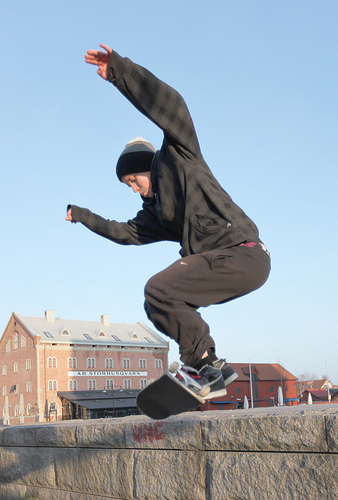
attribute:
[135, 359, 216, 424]
skateboard — inverted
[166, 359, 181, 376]
wheel — white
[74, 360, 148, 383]
sign — white, black letters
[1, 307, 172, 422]
building — large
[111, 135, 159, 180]
hat — black, gray, white striped, knitted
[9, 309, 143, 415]
brick building — large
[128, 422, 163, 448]
graffiti — red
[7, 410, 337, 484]
wall — grey, rock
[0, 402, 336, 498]
fence — stone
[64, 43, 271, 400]
person — young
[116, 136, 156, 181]
cap — knitted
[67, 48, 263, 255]
shirt — gray, plaid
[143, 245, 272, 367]
pants — gray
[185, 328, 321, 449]
building — red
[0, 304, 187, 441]
building — large, multi-storied, brick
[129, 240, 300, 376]
pants — black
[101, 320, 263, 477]
skateboard — upside down, gray, brown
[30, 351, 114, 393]
wall — stone, faux stone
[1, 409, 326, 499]
pattern — rectangular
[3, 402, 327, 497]
wall — stone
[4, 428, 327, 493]
wall — stone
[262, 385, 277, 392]
items — blue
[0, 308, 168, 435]
building — brick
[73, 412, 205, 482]
wall — stone